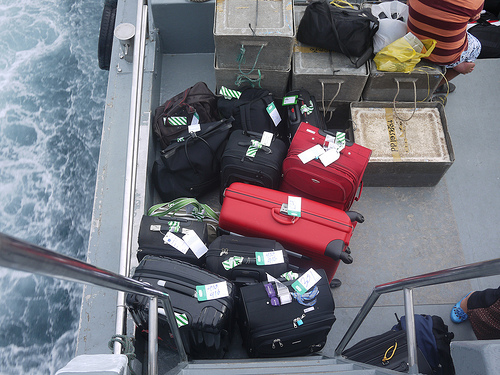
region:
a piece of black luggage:
[125, 255, 237, 360]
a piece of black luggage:
[225, 262, 336, 354]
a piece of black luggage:
[341, 315, 446, 370]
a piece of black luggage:
[135, 210, 210, 265]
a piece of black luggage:
[200, 234, 287, 286]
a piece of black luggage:
[220, 123, 282, 189]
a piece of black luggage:
[152, 115, 233, 196]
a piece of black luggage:
[213, 86, 315, 140]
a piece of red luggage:
[216, 179, 364, 294]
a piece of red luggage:
[281, 117, 373, 212]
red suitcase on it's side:
[215, 174, 372, 289]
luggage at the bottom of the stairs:
[137, 77, 364, 352]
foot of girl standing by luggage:
[429, 267, 498, 340]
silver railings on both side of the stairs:
[4, 222, 498, 372]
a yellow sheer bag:
[363, 28, 440, 85]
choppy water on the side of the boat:
[7, 8, 107, 371]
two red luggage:
[215, 115, 402, 295]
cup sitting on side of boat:
[95, 5, 150, 79]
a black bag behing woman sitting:
[296, 4, 382, 86]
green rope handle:
[224, 35, 274, 77]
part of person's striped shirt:
[425, 2, 459, 32]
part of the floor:
[385, 215, 475, 258]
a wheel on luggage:
[338, 248, 360, 268]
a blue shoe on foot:
[447, 296, 463, 323]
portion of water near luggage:
[32, 30, 64, 178]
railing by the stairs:
[5, 238, 118, 294]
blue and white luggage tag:
[252, 251, 282, 271]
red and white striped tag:
[216, 80, 244, 105]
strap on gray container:
[394, 78, 421, 123]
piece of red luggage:
[278, 124, 360, 199]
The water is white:
[4, 30, 76, 212]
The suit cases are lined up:
[131, 185, 349, 353]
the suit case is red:
[201, 168, 371, 256]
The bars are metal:
[303, 245, 498, 340]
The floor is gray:
[380, 198, 499, 286]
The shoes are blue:
[444, 287, 494, 322]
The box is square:
[341, 75, 459, 212]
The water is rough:
[7, 25, 106, 220]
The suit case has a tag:
[186, 271, 230, 308]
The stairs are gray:
[208, 346, 375, 373]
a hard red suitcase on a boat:
[216, 180, 384, 268]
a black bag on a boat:
[295, 2, 380, 65]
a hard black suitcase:
[129, 253, 241, 361]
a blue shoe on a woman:
[442, 289, 474, 322]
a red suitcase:
[283, 118, 389, 208]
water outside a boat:
[2, 0, 105, 372]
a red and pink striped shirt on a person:
[402, 0, 487, 74]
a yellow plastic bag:
[364, 36, 438, 75]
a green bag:
[145, 195, 226, 230]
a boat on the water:
[92, 3, 498, 373]